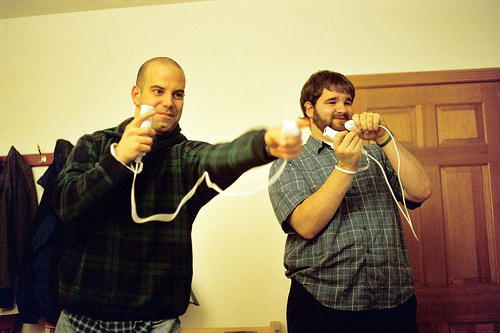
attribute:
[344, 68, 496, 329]
door — wooden, brown, wood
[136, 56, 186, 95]
hair — short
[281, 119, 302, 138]
controller — wii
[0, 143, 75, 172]
rack — coat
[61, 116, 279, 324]
shirt — dark, long sleeved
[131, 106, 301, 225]
wii — nintendo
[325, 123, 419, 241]
wii — nintendo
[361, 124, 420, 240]
cord — white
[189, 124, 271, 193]
arm — extended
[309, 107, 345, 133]
hair — brown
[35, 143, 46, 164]
hook — gold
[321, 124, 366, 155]
remote — white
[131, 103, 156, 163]
remote — white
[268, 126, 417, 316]
shirt — plaid, big, short sleeved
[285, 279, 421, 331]
bottoms — black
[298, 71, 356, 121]
hair — brown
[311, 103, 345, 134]
beard — brown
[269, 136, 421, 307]
shirt — big, plaid, short sleeved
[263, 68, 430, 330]
guy — big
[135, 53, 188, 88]
head — shaved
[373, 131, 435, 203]
arm — man's